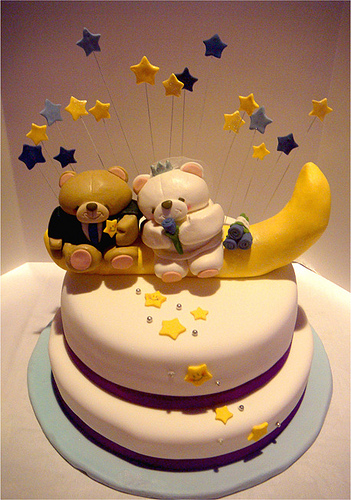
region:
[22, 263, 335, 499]
two layer cake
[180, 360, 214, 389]
smiley face yellow star on cake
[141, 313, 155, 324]
metal ball on top of cake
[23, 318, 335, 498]
blue flat platform under cake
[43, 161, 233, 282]
two teddy bears on top of cake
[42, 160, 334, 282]
two teddy bears on top of moon on top of cake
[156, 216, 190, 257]
blue rose on top of cake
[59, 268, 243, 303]
shadow of teddy bears on cake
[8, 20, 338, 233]
stars on top of cake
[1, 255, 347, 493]
white tablecloth under cake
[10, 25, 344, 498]
two layer cake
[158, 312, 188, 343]
yellow confectionary star on cake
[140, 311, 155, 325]
metal confectionary dot on top of cake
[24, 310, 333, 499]
blue confectionary panel on bottom of cake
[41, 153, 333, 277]
yellow confectionary moon on top of cake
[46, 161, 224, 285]
two teddy bears on top of cake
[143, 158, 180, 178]
blue crown on top of white teddy bear on top of cake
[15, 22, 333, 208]
confectionary star on top of metal pole on top of cake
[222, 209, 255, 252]
three blue towels on the side of teddy bears on top of cake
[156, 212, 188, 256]
blue rose in green holder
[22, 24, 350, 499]
White cake decorated with bears, stars, and moon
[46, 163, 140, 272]
Brown bear wearing a jacket on top of cake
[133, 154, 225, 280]
White bear wearing bridal headpiece on top of cake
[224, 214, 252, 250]
Bouquet of three blue flowers on top of cake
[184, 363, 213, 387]
Smiling yellow star on the side of the second layer of cake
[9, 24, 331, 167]
Group of blue and yellow stars sticking out the top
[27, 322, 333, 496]
Light blue plate with cake sitting on it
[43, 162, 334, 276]
Moon on top of the cake with two bears on it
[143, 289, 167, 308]
Smiling yellow start directly underneath two bears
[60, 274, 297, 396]
Top layer of two layer white cake featuring silver balls and stars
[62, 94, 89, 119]
yellow star over cake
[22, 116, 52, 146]
yellow star over cake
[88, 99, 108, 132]
yellow star over cake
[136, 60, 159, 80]
yellow star over cake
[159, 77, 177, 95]
yellow star over cake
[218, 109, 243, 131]
yellow star over cake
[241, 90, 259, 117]
yellow star over cake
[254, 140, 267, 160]
yellow star over cake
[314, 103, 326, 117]
yellow star over cake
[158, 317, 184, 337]
yellow star on cake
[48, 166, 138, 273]
A brown teddy bear with black coat on.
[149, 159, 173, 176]
A grey crown on a bear.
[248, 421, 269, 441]
The bottom yellow star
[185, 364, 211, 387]
The bottom star with a smiling face.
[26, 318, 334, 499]
Blue round base of a cake.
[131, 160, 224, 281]
A white bear holding a flower with a crown on.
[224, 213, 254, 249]
Three blue roses with green stems.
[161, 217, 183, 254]
A blue flower with green stem a bear holds.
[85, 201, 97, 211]
Brown nose of a brown bear.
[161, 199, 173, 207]
Brown nose on a white bear.